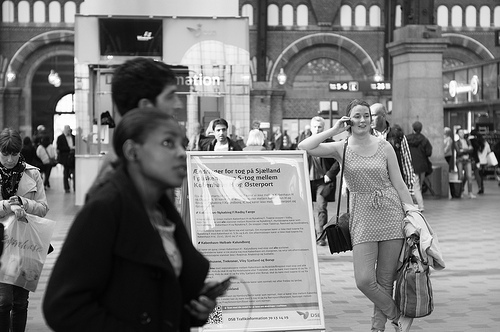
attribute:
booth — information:
[181, 56, 337, 326]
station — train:
[6, 2, 495, 331]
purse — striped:
[395, 234, 435, 321]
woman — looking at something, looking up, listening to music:
[41, 107, 216, 331]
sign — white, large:
[187, 147, 327, 332]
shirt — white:
[214, 143, 229, 152]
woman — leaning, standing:
[297, 97, 414, 330]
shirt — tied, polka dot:
[339, 137, 412, 246]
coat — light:
[399, 199, 447, 276]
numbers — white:
[329, 82, 348, 93]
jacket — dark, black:
[42, 167, 211, 331]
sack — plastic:
[1, 209, 58, 292]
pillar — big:
[383, 1, 449, 198]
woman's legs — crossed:
[349, 237, 407, 331]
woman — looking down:
[0, 128, 52, 332]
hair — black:
[107, 53, 177, 116]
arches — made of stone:
[0, 27, 497, 148]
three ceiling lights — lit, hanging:
[6, 63, 65, 88]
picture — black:
[1, 1, 500, 329]